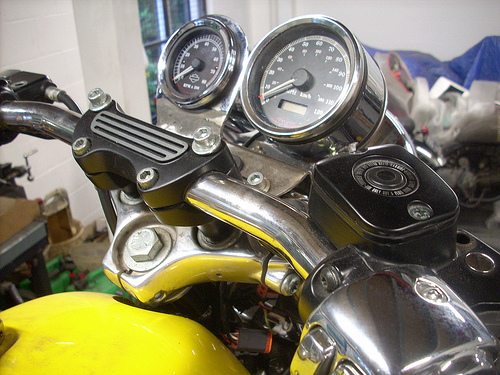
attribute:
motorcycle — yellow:
[1, 14, 498, 374]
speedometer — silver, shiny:
[240, 15, 366, 141]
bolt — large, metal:
[125, 227, 163, 262]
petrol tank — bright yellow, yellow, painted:
[2, 290, 257, 374]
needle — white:
[257, 77, 294, 98]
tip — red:
[257, 94, 261, 100]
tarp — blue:
[361, 35, 499, 89]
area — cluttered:
[352, 1, 499, 208]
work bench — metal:
[1, 197, 55, 297]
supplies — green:
[20, 254, 131, 298]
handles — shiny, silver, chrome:
[0, 66, 497, 373]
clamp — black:
[74, 90, 242, 227]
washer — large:
[123, 228, 172, 272]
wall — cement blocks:
[1, 0, 106, 227]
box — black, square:
[308, 144, 459, 269]